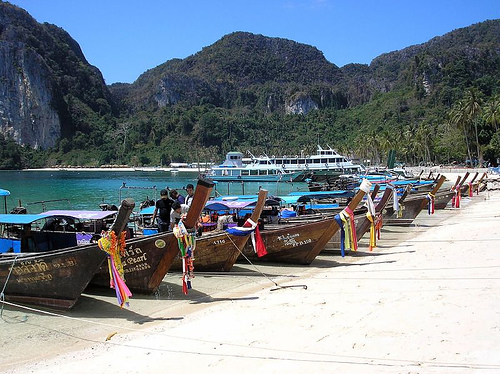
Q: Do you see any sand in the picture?
A: Yes, there is sand.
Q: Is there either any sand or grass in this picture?
A: Yes, there is sand.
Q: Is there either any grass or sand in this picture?
A: Yes, there is sand.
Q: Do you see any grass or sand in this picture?
A: Yes, there is sand.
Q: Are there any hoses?
A: No, there are no hoses.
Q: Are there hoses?
A: No, there are no hoses.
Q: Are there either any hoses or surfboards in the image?
A: No, there are no hoses or surfboards.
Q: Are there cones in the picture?
A: No, there are no cones.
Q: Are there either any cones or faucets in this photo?
A: No, there are no cones or faucets.